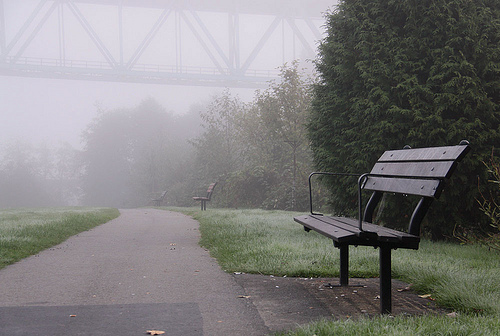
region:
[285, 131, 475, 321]
closer bench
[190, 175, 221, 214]
bench in the middle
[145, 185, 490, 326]
green grass in the right side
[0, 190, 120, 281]
green grass in the left side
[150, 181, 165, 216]
far bench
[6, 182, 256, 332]
road in the middle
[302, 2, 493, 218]
bush in the right side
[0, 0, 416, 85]
bridge on the top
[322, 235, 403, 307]
legs of the bench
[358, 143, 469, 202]
backplate of the bench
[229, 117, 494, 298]
Bench in the ground.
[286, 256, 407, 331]
Bricks under the bench.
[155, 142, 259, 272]
Bench in the background.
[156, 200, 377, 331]
Grass beneath the benches.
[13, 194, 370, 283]
Road between the grass.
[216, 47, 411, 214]
Trees on the road.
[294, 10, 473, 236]
Green tree on the grass.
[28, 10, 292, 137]
Bridge over the road.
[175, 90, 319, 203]
Branches on the tree.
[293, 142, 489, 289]
Metal part of the bench.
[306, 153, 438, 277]
this is a bench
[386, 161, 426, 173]
the bench is made of wood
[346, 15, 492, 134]
this is a tree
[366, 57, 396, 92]
the tree has green leaves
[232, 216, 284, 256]
this is a grass area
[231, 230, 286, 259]
the grass is green in color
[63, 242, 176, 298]
this is a road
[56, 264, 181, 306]
it is a tarmac road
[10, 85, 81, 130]
this is the sky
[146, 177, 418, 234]
the benches are three in number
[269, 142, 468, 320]
The bench is brown with black railing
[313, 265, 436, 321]
The bench is bolted to the ground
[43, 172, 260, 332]
A black asphalt walkway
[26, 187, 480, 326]
The walkway has grass on both sides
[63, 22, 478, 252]
Large trees are behind the benches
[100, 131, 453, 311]
A row of benches follow the pathway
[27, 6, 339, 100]
A bridge goes over the pathway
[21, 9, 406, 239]
A fog is rolling in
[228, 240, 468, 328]
The benches are on cement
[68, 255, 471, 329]
Leaves lie on the asphalt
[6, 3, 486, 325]
a park-like setting on a partially foggy day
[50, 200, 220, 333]
a walkway that curves in the distance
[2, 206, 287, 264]
lush grass on both sides of the walkway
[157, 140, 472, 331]
a bench beside the walkway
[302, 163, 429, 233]
metal armrests of bench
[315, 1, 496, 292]
large shrubbery behind bench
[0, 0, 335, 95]
elevated metal structure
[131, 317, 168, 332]
dry leaf on walkway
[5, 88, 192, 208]
foliage in the distance is obscured by fog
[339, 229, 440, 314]
dry leaves beneath bench